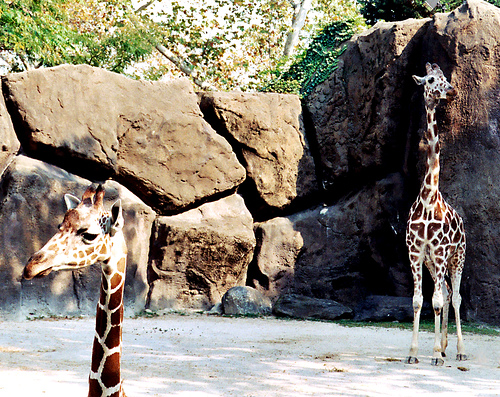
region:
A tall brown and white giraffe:
[402, 77, 480, 361]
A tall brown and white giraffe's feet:
[408, 270, 425, 370]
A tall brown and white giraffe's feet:
[434, 270, 448, 374]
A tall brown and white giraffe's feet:
[450, 270, 471, 362]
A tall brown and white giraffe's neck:
[412, 114, 452, 196]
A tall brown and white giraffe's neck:
[92, 290, 147, 395]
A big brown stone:
[1, 73, 232, 190]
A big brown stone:
[160, 214, 247, 329]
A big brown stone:
[255, 207, 386, 291]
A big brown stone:
[218, 94, 309, 175]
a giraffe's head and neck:
[17, 183, 134, 395]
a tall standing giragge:
[405, 51, 469, 378]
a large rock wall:
[4, 8, 497, 333]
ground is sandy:
[0, 298, 495, 395]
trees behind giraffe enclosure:
[2, 2, 494, 98]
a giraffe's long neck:
[404, 62, 461, 193]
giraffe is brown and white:
[407, 62, 469, 383]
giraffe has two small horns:
[74, 185, 109, 207]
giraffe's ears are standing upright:
[57, 188, 127, 231]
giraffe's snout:
[21, 248, 55, 282]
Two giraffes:
[18, 55, 485, 395]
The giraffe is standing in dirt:
[364, 321, 489, 377]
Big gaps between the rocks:
[195, 93, 261, 203]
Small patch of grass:
[355, 308, 414, 329]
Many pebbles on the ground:
[138, 315, 203, 354]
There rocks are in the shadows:
[299, 65, 482, 310]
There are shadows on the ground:
[142, 311, 377, 387]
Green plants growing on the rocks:
[20, 3, 331, 95]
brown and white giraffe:
[384, 61, 473, 368]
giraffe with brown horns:
[20, 177, 141, 288]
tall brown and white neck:
[417, 98, 453, 196]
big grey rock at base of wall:
[217, 276, 282, 322]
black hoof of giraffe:
[400, 352, 422, 367]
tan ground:
[213, 319, 373, 390]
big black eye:
[82, 230, 104, 247]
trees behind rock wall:
[40, 6, 327, 106]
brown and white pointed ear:
[107, 198, 139, 242]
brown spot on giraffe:
[116, 258, 126, 272]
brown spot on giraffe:
[102, 263, 113, 275]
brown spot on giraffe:
[107, 272, 123, 288]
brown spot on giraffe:
[96, 286, 109, 303]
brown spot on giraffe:
[105, 286, 125, 310]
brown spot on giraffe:
[112, 303, 124, 323]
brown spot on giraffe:
[103, 322, 119, 349]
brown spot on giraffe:
[100, 352, 120, 388]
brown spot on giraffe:
[88, 375, 103, 395]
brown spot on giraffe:
[91, 335, 103, 368]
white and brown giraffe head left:
[21, 200, 126, 279]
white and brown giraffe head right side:
[422, 67, 462, 100]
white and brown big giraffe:
[417, 75, 462, 330]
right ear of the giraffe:
[410, 70, 421, 85]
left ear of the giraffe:
[107, 202, 122, 230]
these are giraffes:
[47, 35, 492, 342]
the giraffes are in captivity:
[43, 41, 493, 371]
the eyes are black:
[59, 229, 143, 254]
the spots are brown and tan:
[32, 174, 214, 393]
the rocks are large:
[97, 66, 310, 253]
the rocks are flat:
[96, 84, 256, 205]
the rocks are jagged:
[132, 58, 283, 226]